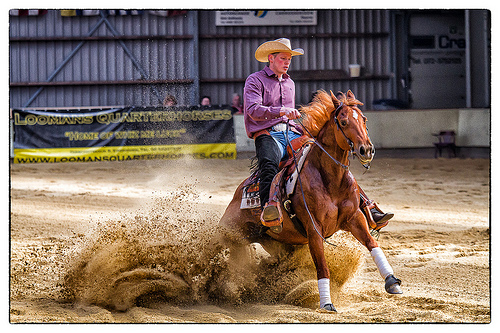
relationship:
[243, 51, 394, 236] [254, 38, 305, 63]
person wearing cowboy hat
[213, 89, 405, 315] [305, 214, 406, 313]
horse has legs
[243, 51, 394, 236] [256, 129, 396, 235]
person has legs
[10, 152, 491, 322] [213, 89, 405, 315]
sand under horse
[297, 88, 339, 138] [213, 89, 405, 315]
hair on horse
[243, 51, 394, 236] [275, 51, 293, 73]
person has face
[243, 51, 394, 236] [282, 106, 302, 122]
person has hand